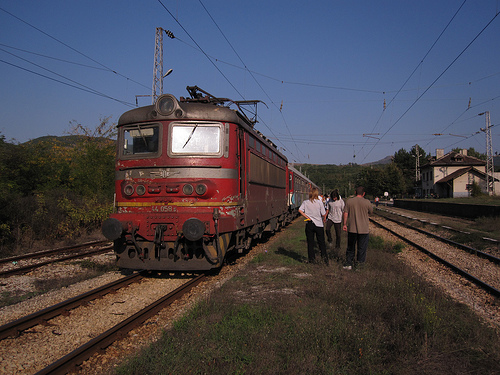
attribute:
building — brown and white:
[416, 148, 499, 198]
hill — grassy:
[2, 131, 111, 253]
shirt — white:
[300, 198, 323, 225]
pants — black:
[305, 219, 326, 261]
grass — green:
[120, 213, 490, 372]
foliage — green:
[125, 213, 499, 370]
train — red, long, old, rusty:
[97, 81, 322, 273]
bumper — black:
[99, 215, 125, 240]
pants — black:
[302, 216, 331, 263]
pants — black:
[323, 215, 343, 248]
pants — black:
[342, 230, 368, 264]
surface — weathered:
[112, 115, 290, 239]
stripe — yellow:
[113, 200, 240, 209]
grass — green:
[124, 230, 497, 371]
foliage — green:
[303, 293, 486, 369]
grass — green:
[60, 142, 114, 182]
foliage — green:
[17, 148, 89, 248]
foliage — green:
[121, 233, 498, 368]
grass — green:
[346, 285, 459, 349]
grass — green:
[250, 268, 350, 357]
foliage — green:
[364, 294, 493, 349]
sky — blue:
[1, 5, 494, 164]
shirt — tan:
[340, 195, 375, 231]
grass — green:
[195, 273, 499, 373]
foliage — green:
[281, 254, 473, 369]